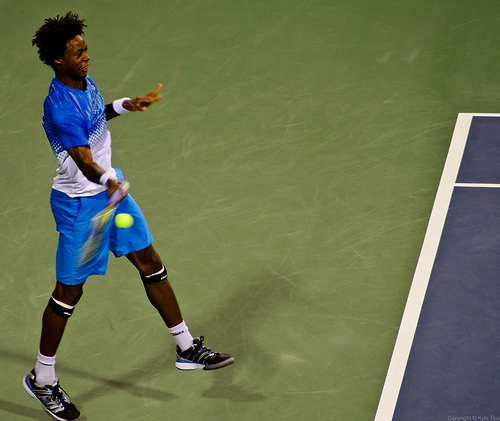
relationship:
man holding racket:
[22, 15, 237, 381] [73, 176, 136, 282]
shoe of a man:
[172, 336, 236, 373] [22, 15, 237, 381]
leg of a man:
[130, 244, 194, 332] [22, 15, 237, 381]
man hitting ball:
[22, 15, 237, 381] [112, 207, 135, 231]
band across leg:
[140, 264, 167, 285] [130, 244, 194, 332]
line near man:
[374, 97, 480, 420] [22, 15, 237, 381]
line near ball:
[374, 97, 480, 420] [112, 207, 135, 231]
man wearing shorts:
[22, 15, 237, 381] [44, 165, 159, 289]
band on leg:
[140, 264, 167, 285] [34, 281, 80, 353]